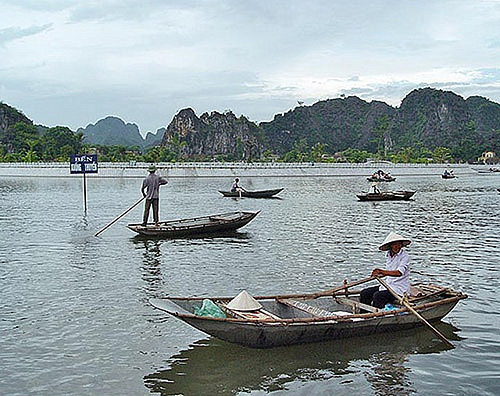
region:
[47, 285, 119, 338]
a body of water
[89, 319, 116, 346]
a body of water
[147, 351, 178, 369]
a body of water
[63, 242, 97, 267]
a body of water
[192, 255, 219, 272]
a body of water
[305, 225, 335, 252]
a body of water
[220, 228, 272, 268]
a body of water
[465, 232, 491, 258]
a body of water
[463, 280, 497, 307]
a body of water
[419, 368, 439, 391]
a body of water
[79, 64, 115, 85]
a clear cloudy sky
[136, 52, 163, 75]
a clear cloudy sky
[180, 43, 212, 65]
a clear cloudy sky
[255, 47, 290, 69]
a clear cloudy sky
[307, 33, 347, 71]
a clear cloudy sky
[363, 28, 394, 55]
a clear cloudy sky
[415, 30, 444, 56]
a clear cloudy sky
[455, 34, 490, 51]
a clear cloudy sky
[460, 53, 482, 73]
a clear cloudy sky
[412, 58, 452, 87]
a clear cloudy sky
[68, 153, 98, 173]
blue sign on a post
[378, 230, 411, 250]
hat to protect from the sun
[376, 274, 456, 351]
a wooden paddle to move a boat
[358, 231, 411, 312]
person paddling a boat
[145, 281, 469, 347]
a canoe style boat in the water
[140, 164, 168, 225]
person standing on a boat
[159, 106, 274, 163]
large rock formation on the side of water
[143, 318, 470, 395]
shadow on the water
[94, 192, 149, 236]
long pole used to push a boat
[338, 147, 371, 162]
green tree by the side of water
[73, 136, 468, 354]
fishermen in boats on water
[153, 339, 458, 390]
reflection in the water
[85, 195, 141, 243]
oar of a fisherman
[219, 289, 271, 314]
hat in a boat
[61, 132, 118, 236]
sign in the water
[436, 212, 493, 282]
ripples in the water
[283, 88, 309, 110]
bird in the sky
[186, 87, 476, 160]
hills along side of water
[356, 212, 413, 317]
fisherman in a boat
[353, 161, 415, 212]
bouy in the water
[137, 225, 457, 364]
man sailing in boat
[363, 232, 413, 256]
rice picking hat on head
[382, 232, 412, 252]
white hat on head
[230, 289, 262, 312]
white hat on boat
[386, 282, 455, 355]
long brown oar in water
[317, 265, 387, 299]
long brown oar in hand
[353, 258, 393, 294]
ends of oars in hands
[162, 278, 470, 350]
small white row boat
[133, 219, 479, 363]
person rowing a boat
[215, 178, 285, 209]
person rowing a boat